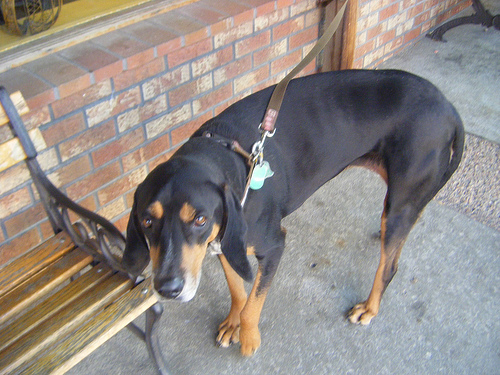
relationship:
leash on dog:
[245, 115, 285, 178] [119, 93, 466, 311]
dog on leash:
[119, 93, 466, 311] [245, 115, 285, 178]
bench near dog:
[5, 193, 113, 335] [119, 93, 466, 311]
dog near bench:
[119, 93, 466, 311] [5, 193, 113, 335]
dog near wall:
[119, 93, 466, 311] [144, 32, 218, 83]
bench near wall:
[5, 193, 113, 335] [144, 32, 218, 83]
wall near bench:
[144, 32, 218, 83] [5, 193, 113, 335]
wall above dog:
[144, 32, 218, 83] [119, 93, 466, 311]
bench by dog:
[5, 193, 113, 335] [119, 93, 466, 311]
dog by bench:
[119, 93, 466, 311] [5, 193, 113, 335]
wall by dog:
[144, 32, 218, 83] [119, 93, 466, 311]